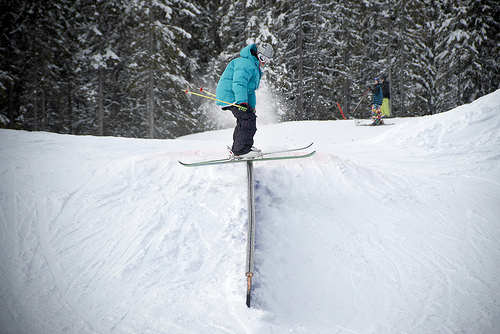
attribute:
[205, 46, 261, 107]
jacket — blue